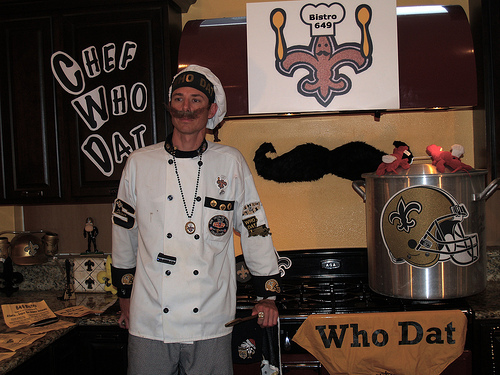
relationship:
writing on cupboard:
[50, 51, 155, 174] [2, 2, 167, 205]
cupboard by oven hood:
[2, 2, 167, 205] [180, 5, 482, 119]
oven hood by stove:
[180, 5, 482, 119] [229, 245, 475, 375]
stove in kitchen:
[229, 245, 475, 375] [1, 0, 496, 373]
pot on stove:
[344, 143, 498, 296] [229, 245, 475, 375]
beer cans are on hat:
[0, 230, 69, 262] [0, 227, 58, 266]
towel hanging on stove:
[296, 309, 469, 375] [229, 245, 475, 375]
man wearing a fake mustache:
[108, 65, 279, 375] [163, 99, 214, 124]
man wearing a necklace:
[108, 65, 279, 375] [167, 140, 213, 240]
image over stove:
[265, 5, 377, 105] [229, 245, 475, 375]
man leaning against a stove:
[108, 65, 279, 375] [229, 245, 475, 375]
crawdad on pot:
[421, 142, 478, 172] [344, 143, 498, 296]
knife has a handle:
[5, 311, 64, 332] [28, 316, 65, 327]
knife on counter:
[5, 311, 64, 332] [0, 285, 135, 374]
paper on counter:
[4, 300, 75, 337] [0, 285, 135, 374]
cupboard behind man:
[2, 2, 167, 205] [108, 65, 279, 375]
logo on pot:
[378, 184, 482, 270] [344, 143, 498, 296]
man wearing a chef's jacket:
[108, 65, 279, 375] [111, 149, 272, 337]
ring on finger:
[254, 310, 265, 321] [256, 310, 265, 330]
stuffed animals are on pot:
[378, 136, 470, 178] [344, 143, 498, 296]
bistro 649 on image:
[299, 11, 339, 36] [265, 5, 377, 105]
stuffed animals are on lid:
[378, 136, 470, 178] [376, 152, 472, 178]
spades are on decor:
[81, 257, 99, 293] [65, 255, 123, 296]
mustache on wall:
[250, 137, 423, 186] [180, 4, 478, 263]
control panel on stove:
[320, 254, 345, 281] [229, 245, 475, 375]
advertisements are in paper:
[22, 49, 453, 153] [4, 300, 75, 337]